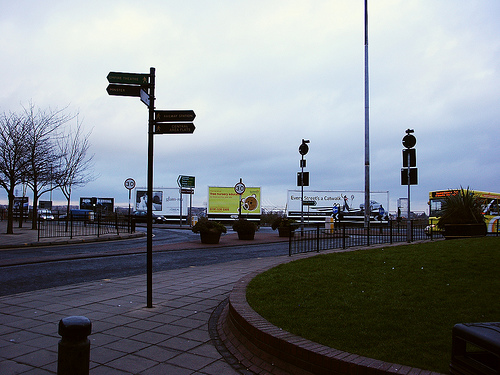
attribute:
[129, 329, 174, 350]
brick — round 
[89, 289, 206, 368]
stone — grey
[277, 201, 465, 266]
gate — black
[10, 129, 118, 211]
trees — bare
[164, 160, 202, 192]
sign — tall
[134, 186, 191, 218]
billboard — distant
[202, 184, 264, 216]
billboard — distant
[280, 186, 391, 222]
billboard — distant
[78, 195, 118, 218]
billboard — distant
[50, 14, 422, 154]
clouds — white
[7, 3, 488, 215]
sky — blue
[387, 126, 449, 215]
sign — tall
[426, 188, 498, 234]
bus — yellow 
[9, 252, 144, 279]
black road — cemented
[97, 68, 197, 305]
sign post — tall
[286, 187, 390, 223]
billboard — white, distant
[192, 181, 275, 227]
billboard — distant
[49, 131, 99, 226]
tree — bare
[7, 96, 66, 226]
tree — bare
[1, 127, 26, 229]
tree — bare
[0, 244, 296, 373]
walkway — stone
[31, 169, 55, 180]
leaves — dry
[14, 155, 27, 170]
leaves — dry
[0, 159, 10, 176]
leaves — dry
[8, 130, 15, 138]
leaves — dry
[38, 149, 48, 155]
leaves — dry